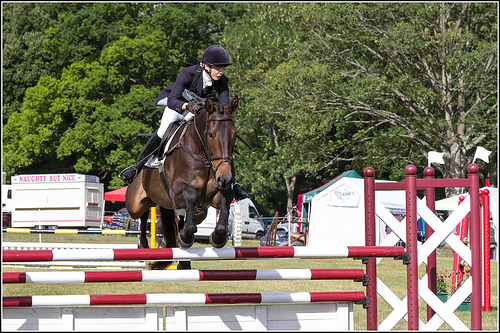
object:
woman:
[118, 44, 250, 203]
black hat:
[200, 44, 234, 82]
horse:
[125, 95, 238, 271]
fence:
[0, 163, 482, 333]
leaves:
[394, 51, 400, 59]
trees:
[234, 0, 500, 234]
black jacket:
[154, 64, 231, 116]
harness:
[193, 101, 237, 171]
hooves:
[175, 233, 195, 250]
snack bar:
[9, 172, 106, 231]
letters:
[63, 174, 67, 181]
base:
[0, 302, 354, 333]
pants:
[156, 106, 184, 140]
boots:
[118, 128, 166, 181]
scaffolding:
[363, 162, 483, 333]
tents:
[305, 176, 411, 247]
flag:
[473, 145, 492, 163]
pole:
[0, 227, 152, 236]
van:
[193, 197, 266, 241]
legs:
[174, 178, 201, 250]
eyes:
[208, 132, 213, 138]